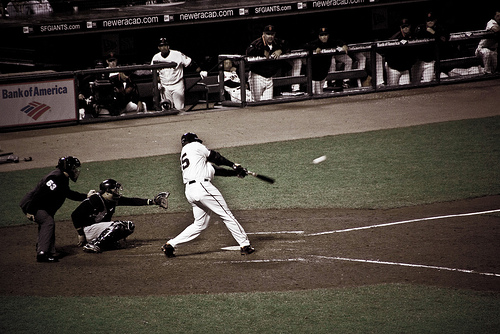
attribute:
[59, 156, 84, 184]
helmet — worn, black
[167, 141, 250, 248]
uniform — white, worn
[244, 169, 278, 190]
bat — held, black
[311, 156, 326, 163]
ball — hit, white, mid-air, moving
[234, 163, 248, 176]
glove — worn, brown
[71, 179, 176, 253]
man — squatting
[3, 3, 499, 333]
game — played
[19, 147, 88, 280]
umpire — preparing, proffesional, prepared, qualified, behind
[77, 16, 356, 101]
players — observing, watching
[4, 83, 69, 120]
advert — red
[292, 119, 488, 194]
grass — green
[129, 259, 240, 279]
dirt — brown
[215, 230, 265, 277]
plate — home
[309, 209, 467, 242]
line — white, white\